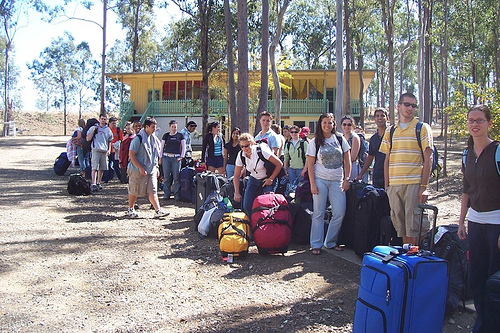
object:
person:
[380, 88, 435, 249]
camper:
[307, 108, 356, 253]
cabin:
[102, 67, 379, 136]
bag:
[218, 206, 251, 259]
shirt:
[372, 115, 435, 187]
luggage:
[353, 242, 449, 333]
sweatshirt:
[125, 125, 165, 171]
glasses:
[467, 117, 485, 124]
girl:
[456, 102, 499, 332]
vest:
[460, 140, 500, 214]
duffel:
[251, 191, 295, 254]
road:
[1, 135, 478, 332]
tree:
[25, 28, 94, 136]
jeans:
[305, 178, 348, 251]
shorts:
[120, 160, 162, 198]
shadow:
[61, 213, 131, 225]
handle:
[416, 203, 440, 249]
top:
[282, 134, 311, 169]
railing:
[151, 98, 328, 116]